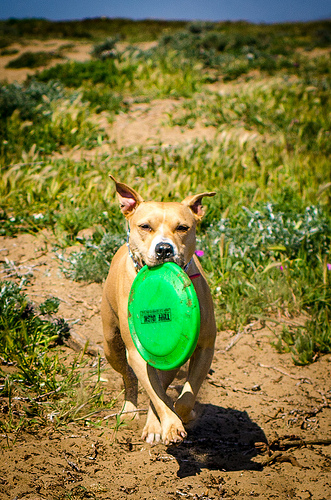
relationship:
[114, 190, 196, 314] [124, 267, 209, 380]
dog holding frisbee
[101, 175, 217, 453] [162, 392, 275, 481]
dog has shadow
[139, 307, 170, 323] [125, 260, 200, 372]
writing on frisbee